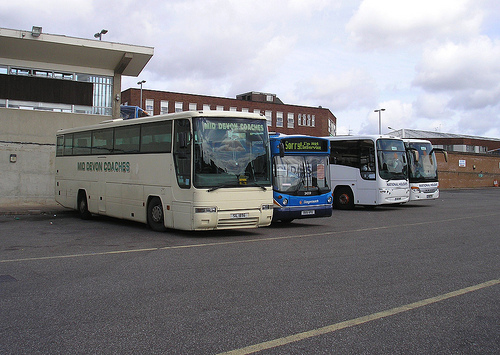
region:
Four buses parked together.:
[45, 110, 456, 225]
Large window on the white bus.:
[182, 104, 270, 201]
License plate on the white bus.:
[223, 206, 250, 223]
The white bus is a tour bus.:
[47, 95, 269, 225]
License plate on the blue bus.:
[297, 205, 318, 221]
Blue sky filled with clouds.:
[302, 5, 461, 79]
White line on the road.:
[362, 271, 485, 333]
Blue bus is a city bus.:
[275, 117, 340, 230]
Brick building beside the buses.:
[442, 120, 492, 197]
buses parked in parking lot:
[45, 106, 445, 241]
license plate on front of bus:
[298, 205, 322, 219]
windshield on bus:
[201, 123, 268, 185]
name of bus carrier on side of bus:
[68, 157, 138, 175]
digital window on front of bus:
[281, 137, 330, 152]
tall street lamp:
[365, 104, 389, 135]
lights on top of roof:
[86, 24, 113, 42]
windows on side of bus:
[59, 119, 172, 161]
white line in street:
[241, 279, 496, 354]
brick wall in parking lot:
[439, 146, 496, 195]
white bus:
[61, 81, 286, 256]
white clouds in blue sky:
[412, 23, 470, 57]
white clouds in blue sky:
[415, 88, 430, 112]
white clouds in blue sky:
[398, 12, 453, 64]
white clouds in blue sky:
[167, 6, 231, 54]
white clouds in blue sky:
[227, 25, 281, 67]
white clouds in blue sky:
[307, 21, 378, 73]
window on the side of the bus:
[53, 137, 62, 153]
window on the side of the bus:
[62, 134, 70, 155]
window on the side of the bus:
[73, 131, 92, 154]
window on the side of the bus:
[90, 128, 110, 156]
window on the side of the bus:
[112, 122, 139, 153]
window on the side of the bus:
[140, 119, 174, 151]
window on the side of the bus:
[337, 151, 362, 169]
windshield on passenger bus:
[192, 130, 273, 186]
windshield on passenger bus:
[274, 156, 330, 192]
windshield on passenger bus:
[377, 149, 407, 179]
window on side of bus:
[56, 136, 64, 156]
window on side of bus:
[63, 134, 72, 153]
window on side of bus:
[72, 129, 92, 153]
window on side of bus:
[92, 127, 114, 154]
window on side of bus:
[113, 124, 140, 152]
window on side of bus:
[142, 119, 173, 153]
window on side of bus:
[334, 148, 359, 166]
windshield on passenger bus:
[195, 126, 270, 183]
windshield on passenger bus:
[272, 152, 329, 194]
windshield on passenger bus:
[381, 150, 410, 179]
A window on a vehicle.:
[138, 117, 171, 154]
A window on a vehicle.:
[189, 115, 282, 187]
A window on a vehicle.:
[173, 118, 200, 190]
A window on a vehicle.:
[110, 122, 145, 154]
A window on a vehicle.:
[88, 127, 118, 155]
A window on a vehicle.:
[71, 132, 103, 154]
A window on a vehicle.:
[61, 132, 79, 152]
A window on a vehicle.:
[276, 150, 334, 195]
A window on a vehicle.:
[373, 145, 407, 179]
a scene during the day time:
[5, 3, 496, 353]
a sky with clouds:
[2, 0, 497, 156]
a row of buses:
[43, 97, 453, 257]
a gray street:
[1, 177, 493, 352]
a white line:
[210, 270, 498, 352]